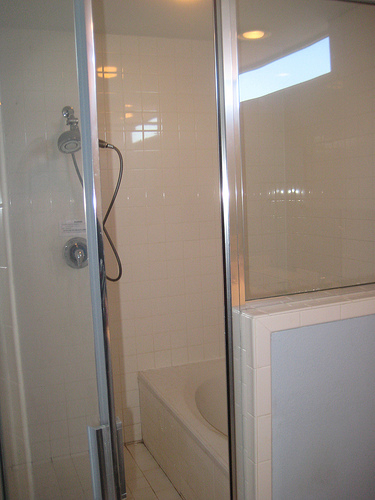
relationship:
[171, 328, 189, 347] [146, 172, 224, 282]
tile on shower wall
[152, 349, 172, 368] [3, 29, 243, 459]
tile on shower wall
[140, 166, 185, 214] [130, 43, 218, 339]
tile on shower wall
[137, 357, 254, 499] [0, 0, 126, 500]
bath tub on door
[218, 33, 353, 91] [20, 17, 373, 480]
window in bathroom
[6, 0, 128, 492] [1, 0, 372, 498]
door in bathroom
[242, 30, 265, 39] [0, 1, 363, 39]
ceiling light on ceiling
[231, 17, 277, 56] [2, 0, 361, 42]
ceiling light on ceiling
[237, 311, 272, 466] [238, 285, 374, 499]
tile on wall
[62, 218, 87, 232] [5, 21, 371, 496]
sticker on shower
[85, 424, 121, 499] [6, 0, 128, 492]
handle on door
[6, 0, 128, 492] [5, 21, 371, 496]
door on shower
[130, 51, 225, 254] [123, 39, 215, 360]
tile on wall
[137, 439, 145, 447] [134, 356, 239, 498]
grout by tub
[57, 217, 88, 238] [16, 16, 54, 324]
tag on wall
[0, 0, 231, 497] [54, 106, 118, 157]
shower has nozzle